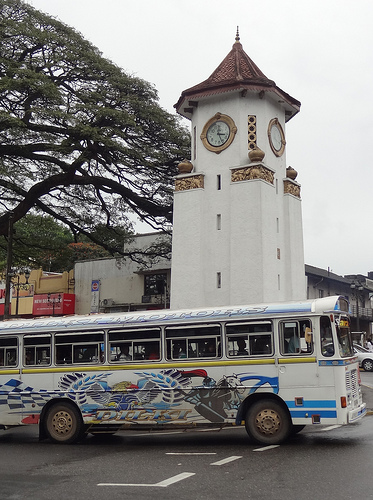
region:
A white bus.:
[3, 294, 364, 447]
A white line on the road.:
[96, 473, 196, 490]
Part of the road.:
[35, 458, 73, 487]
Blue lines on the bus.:
[288, 396, 339, 421]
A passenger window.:
[162, 323, 222, 360]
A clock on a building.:
[200, 109, 238, 153]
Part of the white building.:
[184, 224, 201, 277]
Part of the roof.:
[218, 66, 231, 83]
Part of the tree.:
[65, 84, 153, 160]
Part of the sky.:
[323, 158, 349, 208]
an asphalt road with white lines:
[0, 414, 372, 498]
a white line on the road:
[208, 454, 242, 465]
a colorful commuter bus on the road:
[0, 295, 366, 444]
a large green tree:
[0, 0, 191, 270]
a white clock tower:
[168, 25, 306, 309]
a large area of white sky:
[0, 0, 372, 278]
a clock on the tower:
[206, 120, 230, 147]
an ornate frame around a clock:
[199, 112, 237, 154]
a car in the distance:
[321, 341, 371, 370]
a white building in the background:
[74, 230, 372, 339]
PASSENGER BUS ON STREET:
[1, 292, 367, 442]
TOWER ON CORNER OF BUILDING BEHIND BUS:
[151, 9, 312, 255]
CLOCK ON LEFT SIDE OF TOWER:
[197, 113, 244, 159]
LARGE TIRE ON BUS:
[243, 397, 297, 446]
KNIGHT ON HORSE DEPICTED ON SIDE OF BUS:
[164, 369, 247, 426]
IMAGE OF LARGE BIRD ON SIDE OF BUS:
[58, 370, 183, 413]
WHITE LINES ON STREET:
[91, 432, 314, 494]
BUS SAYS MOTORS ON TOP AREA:
[109, 301, 272, 327]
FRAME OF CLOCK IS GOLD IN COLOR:
[200, 111, 237, 154]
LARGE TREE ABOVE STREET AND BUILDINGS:
[3, 18, 173, 243]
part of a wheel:
[270, 434, 280, 446]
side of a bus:
[218, 381, 222, 385]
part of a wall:
[190, 271, 200, 294]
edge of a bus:
[154, 392, 161, 407]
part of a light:
[340, 387, 345, 394]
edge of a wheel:
[252, 414, 258, 427]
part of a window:
[281, 322, 286, 337]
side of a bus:
[275, 347, 290, 379]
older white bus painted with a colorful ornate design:
[7, 290, 371, 441]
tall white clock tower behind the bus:
[148, 15, 327, 307]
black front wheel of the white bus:
[236, 394, 290, 449]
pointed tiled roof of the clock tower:
[176, 22, 297, 105]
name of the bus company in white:
[4, 303, 264, 328]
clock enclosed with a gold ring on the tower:
[196, 110, 239, 157]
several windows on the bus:
[55, 317, 280, 368]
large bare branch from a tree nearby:
[12, 163, 166, 228]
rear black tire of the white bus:
[36, 399, 83, 445]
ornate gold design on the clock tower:
[242, 112, 260, 155]